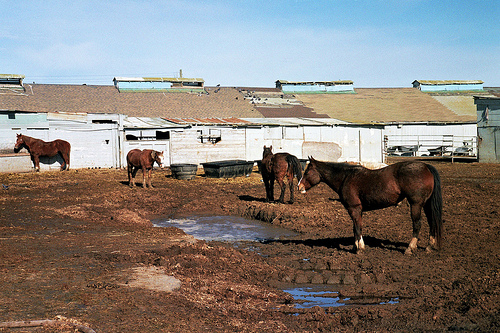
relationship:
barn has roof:
[0, 73, 500, 172] [0, 74, 480, 124]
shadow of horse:
[260, 235, 431, 256] [299, 156, 444, 254]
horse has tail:
[299, 156, 444, 254] [429, 164, 444, 251]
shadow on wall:
[418, 154, 478, 164] [472, 86, 500, 164]